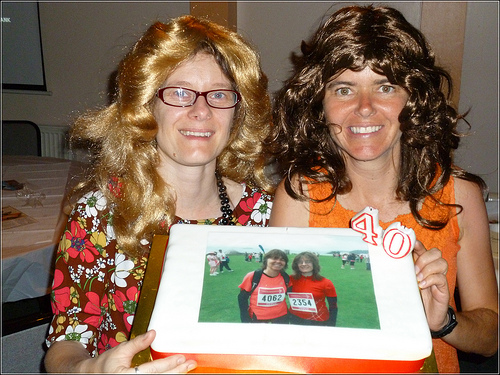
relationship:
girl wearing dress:
[262, 10, 499, 374] [307, 158, 461, 375]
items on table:
[2, 175, 49, 229] [4, 152, 75, 254]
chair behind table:
[34, 65, 153, 162] [14, 101, 102, 264]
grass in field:
[166, 245, 381, 362] [207, 223, 374, 342]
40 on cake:
[353, 201, 408, 254] [169, 213, 430, 360]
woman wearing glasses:
[40, 12, 271, 372] [156, 85, 241, 115]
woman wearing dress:
[40, 13, 270, 375] [88, 193, 203, 340]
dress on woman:
[42, 184, 275, 355] [83, 17, 270, 220]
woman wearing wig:
[40, 12, 271, 372] [80, 9, 284, 242]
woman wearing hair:
[40, 12, 271, 372] [253, 3, 492, 231]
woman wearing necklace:
[40, 13, 270, 375] [200, 161, 235, 229]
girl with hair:
[262, 3, 499, 374] [258, 0, 497, 230]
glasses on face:
[143, 81, 244, 108] [131, 30, 243, 171]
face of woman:
[131, 30, 243, 171] [36, 15, 296, 368]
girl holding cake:
[262, 3, 499, 374] [133, 209, 436, 371]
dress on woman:
[307, 158, 461, 375] [289, 7, 419, 374]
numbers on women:
[254, 285, 320, 313] [132, 34, 486, 259]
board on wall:
[0, 1, 53, 93] [49, 11, 104, 83]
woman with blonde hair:
[40, 12, 271, 372] [78, 10, 276, 254]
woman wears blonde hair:
[40, 12, 271, 372] [66, 15, 275, 257]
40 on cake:
[351, 207, 416, 259] [130, 187, 436, 374]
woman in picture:
[244, 247, 287, 310] [190, 232, 385, 335]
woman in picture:
[291, 249, 340, 319] [190, 232, 385, 335]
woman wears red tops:
[286, 250, 339, 327] [244, 272, 336, 322]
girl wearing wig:
[262, 3, 499, 374] [258, 2, 487, 235]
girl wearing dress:
[262, 3, 499, 374] [299, 146, 466, 367]